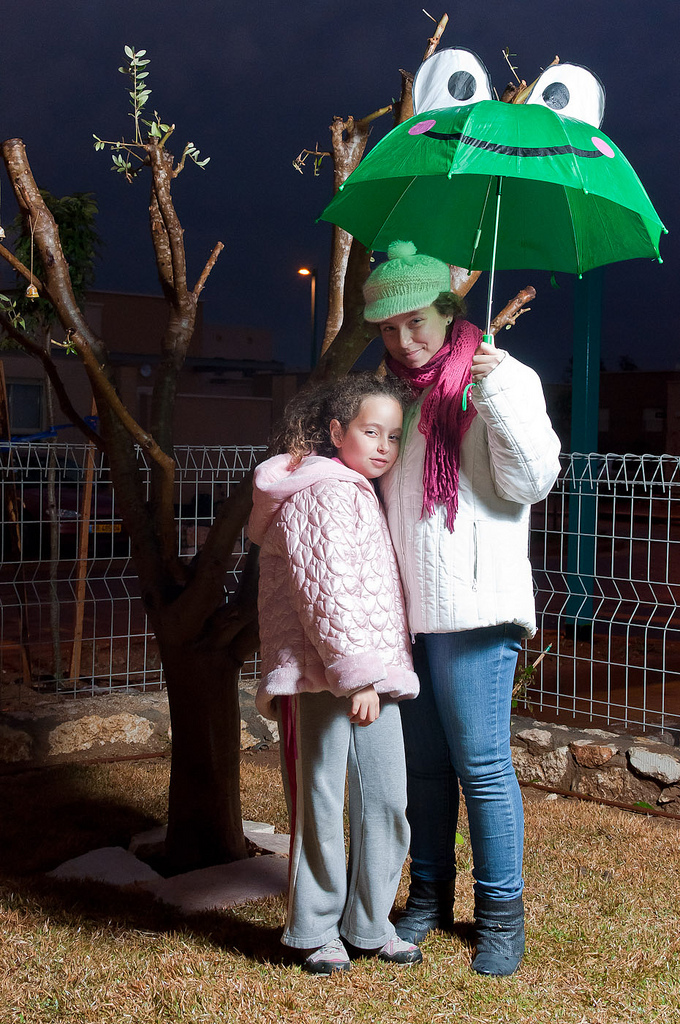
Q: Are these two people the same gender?
A: Yes, all the people are female.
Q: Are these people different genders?
A: No, all the people are female.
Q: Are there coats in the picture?
A: Yes, there is a coat.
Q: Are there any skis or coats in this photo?
A: Yes, there is a coat.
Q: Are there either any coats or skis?
A: Yes, there is a coat.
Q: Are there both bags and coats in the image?
A: No, there is a coat but no bags.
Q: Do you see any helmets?
A: No, there are no helmets.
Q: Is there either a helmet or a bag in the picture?
A: No, there are no helmets or bags.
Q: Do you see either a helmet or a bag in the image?
A: No, there are no helmets or bags.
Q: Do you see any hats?
A: Yes, there is a hat.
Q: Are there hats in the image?
A: Yes, there is a hat.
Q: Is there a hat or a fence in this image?
A: Yes, there is a hat.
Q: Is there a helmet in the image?
A: No, there are no helmets.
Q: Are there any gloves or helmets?
A: No, there are no helmets or gloves.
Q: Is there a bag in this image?
A: No, there are no bags.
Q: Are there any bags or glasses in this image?
A: No, there are no bags or glasses.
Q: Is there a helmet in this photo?
A: No, there are no helmets.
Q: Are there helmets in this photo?
A: No, there are no helmets.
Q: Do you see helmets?
A: No, there are no helmets.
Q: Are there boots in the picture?
A: Yes, there are boots.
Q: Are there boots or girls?
A: Yes, there are boots.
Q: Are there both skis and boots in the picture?
A: No, there are boots but no skis.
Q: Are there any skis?
A: No, there are no skis.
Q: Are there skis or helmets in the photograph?
A: No, there are no skis or helmets.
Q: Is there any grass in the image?
A: Yes, there is grass.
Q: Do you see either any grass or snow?
A: Yes, there is grass.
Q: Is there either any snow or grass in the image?
A: Yes, there is grass.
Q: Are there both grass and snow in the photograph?
A: No, there is grass but no snow.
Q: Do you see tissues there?
A: No, there are no tissues.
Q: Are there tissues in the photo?
A: No, there are no tissues.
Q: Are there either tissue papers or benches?
A: No, there are no tissue papers or benches.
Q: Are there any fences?
A: Yes, there is a fence.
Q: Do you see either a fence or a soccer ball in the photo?
A: Yes, there is a fence.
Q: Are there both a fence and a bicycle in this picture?
A: No, there is a fence but no bicycles.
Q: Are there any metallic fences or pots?
A: Yes, there is a metal fence.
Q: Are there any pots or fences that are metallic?
A: Yes, the fence is metallic.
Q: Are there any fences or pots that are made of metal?
A: Yes, the fence is made of metal.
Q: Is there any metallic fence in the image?
A: Yes, there is a metal fence.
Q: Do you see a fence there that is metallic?
A: Yes, there is a fence that is metallic.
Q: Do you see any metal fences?
A: Yes, there is a fence that is made of metal.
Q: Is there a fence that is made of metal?
A: Yes, there is a fence that is made of metal.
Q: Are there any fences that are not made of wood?
A: Yes, there is a fence that is made of metal.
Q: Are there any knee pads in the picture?
A: No, there are no knee pads.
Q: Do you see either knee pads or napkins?
A: No, there are no knee pads or napkins.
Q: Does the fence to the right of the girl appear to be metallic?
A: Yes, the fence is metallic.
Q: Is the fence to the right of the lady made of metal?
A: Yes, the fence is made of metal.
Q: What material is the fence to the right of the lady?
A: The fence is made of metal.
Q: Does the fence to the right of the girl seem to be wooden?
A: No, the fence is metallic.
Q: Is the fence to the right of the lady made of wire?
A: No, the fence is made of metal.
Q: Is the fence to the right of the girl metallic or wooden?
A: The fence is metallic.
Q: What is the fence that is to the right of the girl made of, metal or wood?
A: The fence is made of metal.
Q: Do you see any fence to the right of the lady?
A: Yes, there is a fence to the right of the lady.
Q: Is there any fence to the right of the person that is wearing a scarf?
A: Yes, there is a fence to the right of the lady.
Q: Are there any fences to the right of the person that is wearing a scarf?
A: Yes, there is a fence to the right of the lady.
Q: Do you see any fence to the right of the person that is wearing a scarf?
A: Yes, there is a fence to the right of the lady.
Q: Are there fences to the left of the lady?
A: No, the fence is to the right of the lady.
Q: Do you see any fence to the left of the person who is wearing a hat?
A: No, the fence is to the right of the lady.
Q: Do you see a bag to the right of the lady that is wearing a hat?
A: No, there is a fence to the right of the lady.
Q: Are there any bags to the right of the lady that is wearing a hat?
A: No, there is a fence to the right of the lady.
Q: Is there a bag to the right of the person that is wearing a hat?
A: No, there is a fence to the right of the lady.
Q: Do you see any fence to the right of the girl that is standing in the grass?
A: Yes, there is a fence to the right of the girl.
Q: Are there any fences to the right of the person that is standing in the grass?
A: Yes, there is a fence to the right of the girl.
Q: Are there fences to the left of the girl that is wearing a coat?
A: No, the fence is to the right of the girl.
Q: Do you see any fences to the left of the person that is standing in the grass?
A: No, the fence is to the right of the girl.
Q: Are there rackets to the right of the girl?
A: No, there is a fence to the right of the girl.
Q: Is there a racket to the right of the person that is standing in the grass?
A: No, there is a fence to the right of the girl.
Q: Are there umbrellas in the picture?
A: Yes, there is an umbrella.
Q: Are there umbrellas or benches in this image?
A: Yes, there is an umbrella.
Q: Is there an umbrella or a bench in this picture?
A: Yes, there is an umbrella.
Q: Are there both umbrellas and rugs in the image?
A: No, there is an umbrella but no rugs.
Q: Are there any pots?
A: No, there are no pots.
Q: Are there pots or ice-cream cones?
A: No, there are no pots or ice-cream cones.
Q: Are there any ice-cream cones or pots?
A: No, there are no pots or ice-cream cones.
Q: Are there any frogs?
A: Yes, there is a frog.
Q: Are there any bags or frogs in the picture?
A: Yes, there is a frog.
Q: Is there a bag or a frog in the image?
A: Yes, there is a frog.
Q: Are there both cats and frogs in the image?
A: No, there is a frog but no cats.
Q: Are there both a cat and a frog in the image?
A: No, there is a frog but no cats.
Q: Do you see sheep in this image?
A: No, there are no sheep.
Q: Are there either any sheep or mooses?
A: No, there are no sheep or mooses.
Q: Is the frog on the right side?
A: Yes, the frog is on the right of the image.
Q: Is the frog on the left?
A: No, the frog is on the right of the image.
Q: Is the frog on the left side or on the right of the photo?
A: The frog is on the right of the image.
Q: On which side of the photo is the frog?
A: The frog is on the right of the image.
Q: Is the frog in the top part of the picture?
A: Yes, the frog is in the top of the image.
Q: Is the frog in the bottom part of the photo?
A: No, the frog is in the top of the image.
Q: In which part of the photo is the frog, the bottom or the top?
A: The frog is in the top of the image.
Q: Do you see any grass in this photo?
A: Yes, there is grass.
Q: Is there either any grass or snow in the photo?
A: Yes, there is grass.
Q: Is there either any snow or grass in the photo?
A: Yes, there is grass.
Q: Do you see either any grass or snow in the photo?
A: Yes, there is grass.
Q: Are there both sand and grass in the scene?
A: No, there is grass but no sand.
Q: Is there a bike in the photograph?
A: No, there are no bikes.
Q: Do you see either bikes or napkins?
A: No, there are no bikes or napkins.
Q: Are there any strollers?
A: No, there are no strollers.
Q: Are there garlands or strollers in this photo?
A: No, there are no strollers or garlands.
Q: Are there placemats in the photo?
A: No, there are no placemats.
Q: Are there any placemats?
A: No, there are no placemats.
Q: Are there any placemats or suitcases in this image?
A: No, there are no placemats or suitcases.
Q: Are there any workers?
A: No, there are no workers.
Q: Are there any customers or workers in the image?
A: No, there are no workers or customers.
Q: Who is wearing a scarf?
A: The lady is wearing a scarf.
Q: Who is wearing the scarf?
A: The lady is wearing a scarf.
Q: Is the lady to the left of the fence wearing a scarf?
A: Yes, the lady is wearing a scarf.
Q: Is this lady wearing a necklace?
A: No, the lady is wearing a scarf.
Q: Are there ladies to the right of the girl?
A: Yes, there is a lady to the right of the girl.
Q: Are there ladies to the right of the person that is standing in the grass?
A: Yes, there is a lady to the right of the girl.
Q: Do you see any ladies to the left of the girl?
A: No, the lady is to the right of the girl.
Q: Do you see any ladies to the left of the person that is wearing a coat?
A: No, the lady is to the right of the girl.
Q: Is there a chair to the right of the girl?
A: No, there is a lady to the right of the girl.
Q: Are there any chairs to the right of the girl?
A: No, there is a lady to the right of the girl.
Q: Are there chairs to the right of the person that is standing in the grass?
A: No, there is a lady to the right of the girl.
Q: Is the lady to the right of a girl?
A: Yes, the lady is to the right of a girl.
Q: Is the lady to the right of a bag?
A: No, the lady is to the right of a girl.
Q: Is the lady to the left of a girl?
A: No, the lady is to the right of a girl.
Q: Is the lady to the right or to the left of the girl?
A: The lady is to the right of the girl.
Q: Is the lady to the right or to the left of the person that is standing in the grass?
A: The lady is to the right of the girl.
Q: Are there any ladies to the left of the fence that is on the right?
A: Yes, there is a lady to the left of the fence.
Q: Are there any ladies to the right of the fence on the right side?
A: No, the lady is to the left of the fence.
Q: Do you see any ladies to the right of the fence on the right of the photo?
A: No, the lady is to the left of the fence.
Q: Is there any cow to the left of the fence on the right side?
A: No, there is a lady to the left of the fence.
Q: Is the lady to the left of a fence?
A: Yes, the lady is to the left of a fence.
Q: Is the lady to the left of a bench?
A: No, the lady is to the left of a fence.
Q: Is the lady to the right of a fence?
A: No, the lady is to the left of a fence.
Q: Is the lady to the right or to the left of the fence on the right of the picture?
A: The lady is to the left of the fence.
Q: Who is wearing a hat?
A: The lady is wearing a hat.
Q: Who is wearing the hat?
A: The lady is wearing a hat.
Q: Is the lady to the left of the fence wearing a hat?
A: Yes, the lady is wearing a hat.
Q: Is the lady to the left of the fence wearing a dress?
A: No, the lady is wearing a hat.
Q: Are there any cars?
A: No, there are no cars.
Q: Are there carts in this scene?
A: No, there are no carts.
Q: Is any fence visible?
A: Yes, there is a fence.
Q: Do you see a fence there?
A: Yes, there is a fence.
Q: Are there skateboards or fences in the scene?
A: Yes, there is a fence.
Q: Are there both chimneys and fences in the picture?
A: No, there is a fence but no chimneys.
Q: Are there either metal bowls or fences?
A: Yes, there is a metal fence.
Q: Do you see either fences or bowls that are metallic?
A: Yes, the fence is metallic.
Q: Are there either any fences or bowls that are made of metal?
A: Yes, the fence is made of metal.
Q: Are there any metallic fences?
A: Yes, there is a metal fence.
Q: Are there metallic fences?
A: Yes, there is a metal fence.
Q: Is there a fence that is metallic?
A: Yes, there is a fence that is metallic.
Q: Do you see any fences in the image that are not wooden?
A: Yes, there is a metallic fence.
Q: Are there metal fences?
A: Yes, there is a fence that is made of metal.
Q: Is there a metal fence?
A: Yes, there is a fence that is made of metal.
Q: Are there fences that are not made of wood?
A: Yes, there is a fence that is made of metal.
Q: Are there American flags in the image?
A: No, there are no American flags.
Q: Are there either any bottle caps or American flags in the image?
A: No, there are no American flags or bottle caps.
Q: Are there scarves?
A: Yes, there is a scarf.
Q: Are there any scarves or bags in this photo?
A: Yes, there is a scarf.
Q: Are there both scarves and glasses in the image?
A: No, there is a scarf but no glasses.